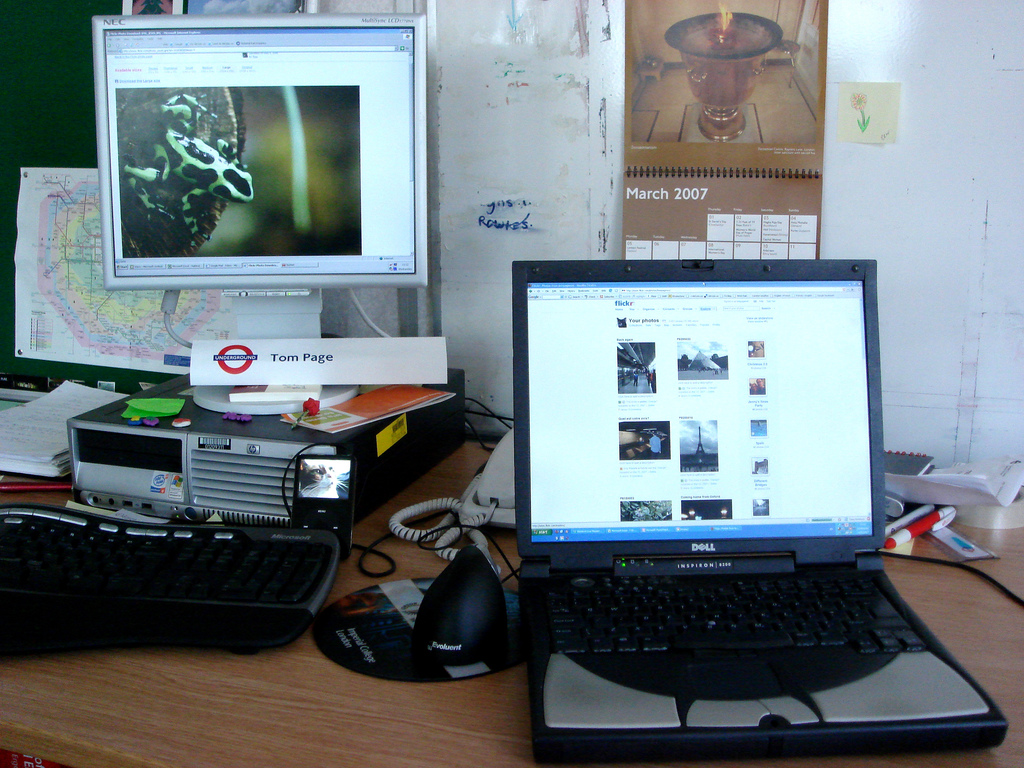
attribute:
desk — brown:
[9, 555, 1018, 763]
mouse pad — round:
[317, 570, 529, 694]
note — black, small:
[475, 198, 542, 244]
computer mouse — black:
[409, 543, 509, 667]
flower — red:
[289, 378, 331, 430]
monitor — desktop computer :
[509, 262, 892, 546]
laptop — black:
[510, 258, 1007, 756]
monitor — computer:
[82, 52, 437, 297]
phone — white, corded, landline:
[347, 385, 637, 597]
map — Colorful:
[11, 165, 318, 371]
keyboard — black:
[20, 531, 316, 650]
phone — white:
[437, 445, 505, 573]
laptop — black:
[575, 371, 746, 478]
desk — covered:
[43, 408, 903, 705]